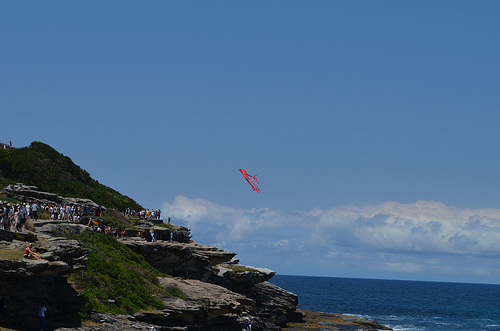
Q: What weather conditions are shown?
A: It is clear.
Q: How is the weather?
A: It is clear.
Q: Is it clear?
A: Yes, it is clear.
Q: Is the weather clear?
A: Yes, it is clear.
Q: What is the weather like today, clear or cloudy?
A: It is clear.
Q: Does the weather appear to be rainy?
A: No, it is clear.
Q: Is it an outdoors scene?
A: Yes, it is outdoors.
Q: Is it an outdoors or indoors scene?
A: It is outdoors.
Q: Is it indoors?
A: No, it is outdoors.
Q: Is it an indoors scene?
A: No, it is outdoors.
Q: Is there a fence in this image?
A: No, there are no fences.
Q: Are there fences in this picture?
A: No, there are no fences.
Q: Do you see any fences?
A: No, there are no fences.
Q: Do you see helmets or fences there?
A: No, there are no fences or helmets.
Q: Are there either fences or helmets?
A: No, there are no fences or helmets.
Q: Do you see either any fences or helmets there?
A: No, there are no fences or helmets.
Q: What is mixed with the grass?
A: The hill is mixed with the grass.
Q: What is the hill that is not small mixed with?
A: The hill is mixed with grass.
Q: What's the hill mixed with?
A: The hill is mixed with grass.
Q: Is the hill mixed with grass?
A: Yes, the hill is mixed with grass.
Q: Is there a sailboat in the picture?
A: No, there are no sailboats.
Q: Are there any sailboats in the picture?
A: No, there are no sailboats.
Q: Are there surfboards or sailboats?
A: No, there are no sailboats or surfboards.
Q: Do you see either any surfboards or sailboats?
A: No, there are no sailboats or surfboards.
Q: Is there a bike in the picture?
A: No, there are no bikes.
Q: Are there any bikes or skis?
A: No, there are no bikes or skis.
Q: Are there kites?
A: Yes, there is a kite.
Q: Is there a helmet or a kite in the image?
A: Yes, there is a kite.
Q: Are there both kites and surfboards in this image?
A: No, there is a kite but no surfboards.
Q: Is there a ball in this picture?
A: No, there are no balls.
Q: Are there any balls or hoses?
A: No, there are no balls or hoses.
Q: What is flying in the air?
A: The kite is flying in the air.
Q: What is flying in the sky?
A: The kite is flying in the sky.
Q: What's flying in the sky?
A: The kite is flying in the sky.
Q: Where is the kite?
A: The kite is in the sky.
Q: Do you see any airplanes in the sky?
A: No, there is a kite in the sky.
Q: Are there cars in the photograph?
A: No, there are no cars.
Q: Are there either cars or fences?
A: No, there are no cars or fences.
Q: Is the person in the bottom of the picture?
A: Yes, the person is in the bottom of the image.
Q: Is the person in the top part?
A: No, the person is in the bottom of the image.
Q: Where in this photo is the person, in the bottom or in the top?
A: The person is in the bottom of the image.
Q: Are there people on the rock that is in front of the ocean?
A: Yes, there is a person on the rock.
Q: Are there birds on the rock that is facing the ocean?
A: No, there is a person on the rock.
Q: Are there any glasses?
A: No, there are no glasses.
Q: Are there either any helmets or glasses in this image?
A: No, there are no glasses or helmets.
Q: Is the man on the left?
A: Yes, the man is on the left of the image.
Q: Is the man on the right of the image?
A: No, the man is on the left of the image.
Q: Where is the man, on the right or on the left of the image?
A: The man is on the left of the image.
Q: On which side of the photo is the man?
A: The man is on the left of the image.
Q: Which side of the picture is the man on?
A: The man is on the left of the image.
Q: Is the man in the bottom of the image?
A: Yes, the man is in the bottom of the image.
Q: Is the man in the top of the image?
A: No, the man is in the bottom of the image.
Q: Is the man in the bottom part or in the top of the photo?
A: The man is in the bottom of the image.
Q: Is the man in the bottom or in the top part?
A: The man is in the bottom of the image.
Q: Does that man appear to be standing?
A: Yes, the man is standing.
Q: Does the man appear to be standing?
A: Yes, the man is standing.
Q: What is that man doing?
A: The man is standing.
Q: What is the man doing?
A: The man is standing.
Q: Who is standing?
A: The man is standing.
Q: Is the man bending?
A: No, the man is standing.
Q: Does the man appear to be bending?
A: No, the man is standing.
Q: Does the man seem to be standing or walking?
A: The man is standing.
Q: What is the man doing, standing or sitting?
A: The man is standing.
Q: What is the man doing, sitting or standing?
A: The man is standing.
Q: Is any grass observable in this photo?
A: Yes, there is grass.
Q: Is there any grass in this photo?
A: Yes, there is grass.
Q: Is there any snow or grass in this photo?
A: Yes, there is grass.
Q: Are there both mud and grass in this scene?
A: No, there is grass but no mud.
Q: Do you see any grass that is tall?
A: Yes, there is tall grass.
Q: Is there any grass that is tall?
A: Yes, there is grass that is tall.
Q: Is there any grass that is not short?
A: Yes, there is tall grass.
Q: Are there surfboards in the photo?
A: No, there are no surfboards.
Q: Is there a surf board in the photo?
A: No, there are no surfboards.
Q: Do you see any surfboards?
A: No, there are no surfboards.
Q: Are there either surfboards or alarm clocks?
A: No, there are no surfboards or alarm clocks.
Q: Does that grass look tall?
A: Yes, the grass is tall.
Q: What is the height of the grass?
A: The grass is tall.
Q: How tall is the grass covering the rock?
A: The grass is tall.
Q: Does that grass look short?
A: No, the grass is tall.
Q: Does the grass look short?
A: No, the grass is tall.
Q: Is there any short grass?
A: No, there is grass but it is tall.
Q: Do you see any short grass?
A: No, there is grass but it is tall.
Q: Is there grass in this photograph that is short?
A: No, there is grass but it is tall.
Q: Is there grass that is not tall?
A: No, there is grass but it is tall.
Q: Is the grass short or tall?
A: The grass is tall.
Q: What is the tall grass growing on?
A: The grass is growing on the rock.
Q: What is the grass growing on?
A: The grass is growing on the rock.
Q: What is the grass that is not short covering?
A: The grass is covering the rock.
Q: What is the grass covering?
A: The grass is covering the rock.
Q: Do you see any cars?
A: No, there are no cars.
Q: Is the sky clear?
A: Yes, the sky is clear.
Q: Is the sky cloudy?
A: No, the sky is clear.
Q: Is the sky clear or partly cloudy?
A: The sky is clear.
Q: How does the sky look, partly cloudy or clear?
A: The sky is clear.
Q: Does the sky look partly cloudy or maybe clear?
A: The sky is clear.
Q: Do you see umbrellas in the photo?
A: No, there are no umbrellas.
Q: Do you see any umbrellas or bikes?
A: No, there are no umbrellas or bikes.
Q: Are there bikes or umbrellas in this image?
A: No, there are no umbrellas or bikes.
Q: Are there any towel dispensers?
A: No, there are no towel dispensers.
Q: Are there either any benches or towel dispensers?
A: No, there are no towel dispensers or benches.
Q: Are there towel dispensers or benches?
A: No, there are no towel dispensers or benches.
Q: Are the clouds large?
A: Yes, the clouds are large.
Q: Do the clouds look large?
A: Yes, the clouds are large.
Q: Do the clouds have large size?
A: Yes, the clouds are large.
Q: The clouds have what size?
A: The clouds are large.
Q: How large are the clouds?
A: The clouds are large.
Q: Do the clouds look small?
A: No, the clouds are large.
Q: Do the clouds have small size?
A: No, the clouds are large.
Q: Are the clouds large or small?
A: The clouds are large.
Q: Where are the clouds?
A: The clouds are in the sky.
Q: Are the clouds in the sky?
A: Yes, the clouds are in the sky.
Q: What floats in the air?
A: The clouds float in the air.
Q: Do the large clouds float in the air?
A: Yes, the clouds float in the air.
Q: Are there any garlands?
A: No, there are no garlands.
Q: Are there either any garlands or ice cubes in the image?
A: No, there are no garlands or ice cubes.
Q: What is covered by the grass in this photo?
A: The rock is covered by the grass.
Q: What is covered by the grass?
A: The rock is covered by the grass.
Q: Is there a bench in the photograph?
A: No, there are no benches.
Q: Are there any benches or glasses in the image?
A: No, there are no benches or glasses.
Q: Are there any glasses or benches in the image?
A: No, there are no benches or glasses.